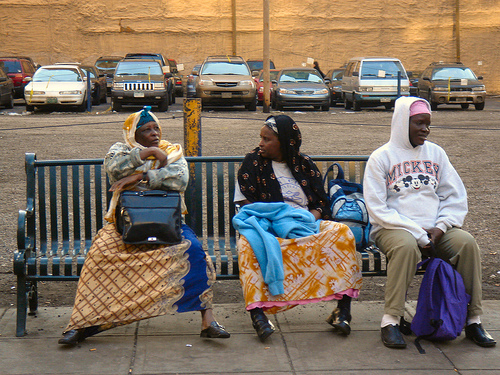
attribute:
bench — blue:
[8, 147, 101, 276]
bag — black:
[113, 186, 184, 250]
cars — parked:
[11, 47, 475, 111]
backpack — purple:
[417, 249, 465, 350]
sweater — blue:
[229, 197, 324, 270]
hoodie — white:
[366, 97, 461, 245]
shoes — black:
[63, 308, 499, 357]